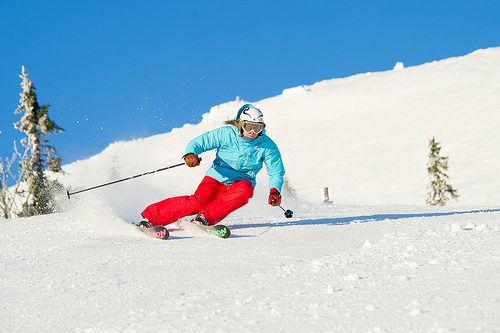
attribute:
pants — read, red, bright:
[139, 175, 257, 228]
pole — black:
[65, 153, 205, 201]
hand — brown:
[179, 151, 202, 168]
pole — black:
[268, 197, 296, 220]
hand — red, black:
[266, 188, 284, 207]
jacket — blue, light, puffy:
[181, 122, 286, 197]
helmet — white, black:
[235, 106, 268, 144]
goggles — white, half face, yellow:
[236, 117, 266, 138]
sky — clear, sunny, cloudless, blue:
[0, 1, 499, 191]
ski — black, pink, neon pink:
[132, 217, 171, 243]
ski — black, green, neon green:
[180, 217, 233, 242]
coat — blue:
[184, 123, 287, 200]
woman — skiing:
[138, 105, 286, 231]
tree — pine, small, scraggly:
[422, 138, 461, 210]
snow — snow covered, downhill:
[1, 46, 497, 329]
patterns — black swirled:
[233, 104, 268, 123]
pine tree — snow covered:
[1, 63, 86, 219]